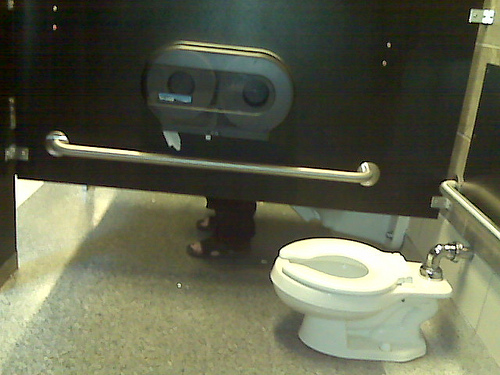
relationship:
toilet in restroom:
[269, 228, 478, 367] [9, 6, 483, 375]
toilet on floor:
[269, 228, 478, 367] [99, 265, 208, 339]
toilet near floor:
[269, 228, 478, 367] [99, 265, 208, 339]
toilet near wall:
[269, 228, 478, 367] [295, 16, 454, 155]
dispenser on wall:
[145, 46, 293, 158] [295, 16, 454, 155]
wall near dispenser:
[295, 16, 454, 155] [145, 46, 293, 158]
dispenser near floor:
[145, 46, 293, 158] [99, 265, 208, 339]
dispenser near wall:
[145, 46, 293, 158] [295, 16, 454, 155]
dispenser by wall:
[145, 46, 293, 158] [295, 16, 454, 155]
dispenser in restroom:
[145, 46, 293, 158] [9, 6, 483, 375]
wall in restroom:
[295, 16, 454, 155] [9, 6, 483, 375]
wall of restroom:
[295, 16, 454, 155] [9, 6, 483, 375]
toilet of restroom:
[269, 228, 478, 367] [9, 6, 483, 375]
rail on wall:
[40, 130, 382, 192] [0, 0, 488, 273]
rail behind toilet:
[437, 173, 499, 263] [266, 233, 460, 359]